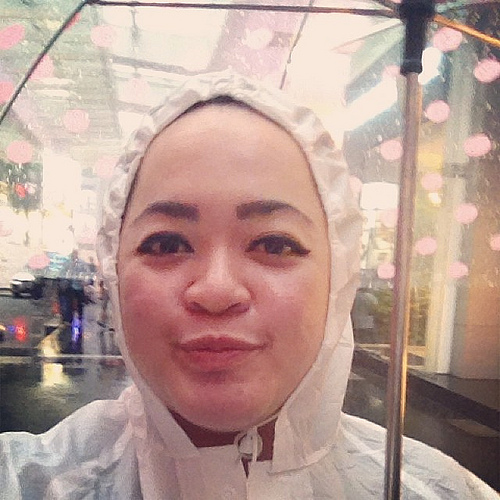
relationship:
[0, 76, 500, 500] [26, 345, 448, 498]
person wearing poncho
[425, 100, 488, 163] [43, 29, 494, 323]
polka dots on umbrella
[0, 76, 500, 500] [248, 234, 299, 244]
person wears eyeliner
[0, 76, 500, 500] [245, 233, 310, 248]
person ears eyelashes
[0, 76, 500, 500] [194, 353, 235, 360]
person wearing lipstick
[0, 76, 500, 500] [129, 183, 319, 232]
person has eyebrowns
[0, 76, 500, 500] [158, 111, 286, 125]
person have hairline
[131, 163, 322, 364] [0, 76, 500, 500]
face on person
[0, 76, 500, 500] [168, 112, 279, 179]
person has forehead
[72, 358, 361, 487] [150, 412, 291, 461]
hood around neck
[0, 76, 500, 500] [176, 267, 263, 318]
person has nose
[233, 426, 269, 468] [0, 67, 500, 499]
tie on poncho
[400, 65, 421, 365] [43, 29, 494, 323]
pole on umbrella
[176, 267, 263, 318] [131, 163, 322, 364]
nose on face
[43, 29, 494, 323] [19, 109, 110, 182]
umbrella has spots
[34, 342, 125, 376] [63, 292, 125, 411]
lines on road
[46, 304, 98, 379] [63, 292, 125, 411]
reflection on road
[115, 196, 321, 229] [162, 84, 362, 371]
eyebrows on person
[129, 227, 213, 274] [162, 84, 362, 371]
eye on person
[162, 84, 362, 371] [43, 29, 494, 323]
person under umbrella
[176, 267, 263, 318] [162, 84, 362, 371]
nose on person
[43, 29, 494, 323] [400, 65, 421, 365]
umbrella has pole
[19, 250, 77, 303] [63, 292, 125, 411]
car on road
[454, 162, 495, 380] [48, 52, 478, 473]
wall in photo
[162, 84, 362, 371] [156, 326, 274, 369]
person has mouth